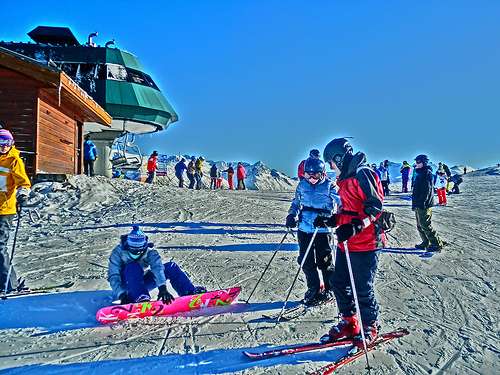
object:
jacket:
[284, 175, 346, 234]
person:
[312, 134, 386, 344]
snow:
[286, 260, 495, 374]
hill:
[227, 160, 297, 193]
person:
[104, 223, 209, 304]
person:
[0, 126, 33, 301]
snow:
[24, 168, 491, 373]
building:
[0, 46, 116, 176]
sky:
[1, 0, 499, 195]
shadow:
[144, 210, 248, 239]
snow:
[400, 254, 498, 349]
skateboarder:
[93, 284, 243, 326]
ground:
[18, 169, 498, 366]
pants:
[120, 261, 197, 305]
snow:
[0, 135, 495, 374]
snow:
[172, 203, 258, 253]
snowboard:
[99, 279, 239, 330]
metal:
[109, 129, 143, 170]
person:
[410, 153, 445, 253]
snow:
[4, 158, 498, 365]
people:
[0, 119, 468, 354]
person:
[235, 164, 248, 191]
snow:
[186, 191, 280, 204]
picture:
[2, 1, 496, 373]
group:
[142, 148, 250, 190]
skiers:
[319, 139, 388, 348]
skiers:
[284, 149, 345, 301]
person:
[144, 150, 158, 184]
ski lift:
[108, 134, 141, 173]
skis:
[244, 327, 408, 374]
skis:
[267, 288, 332, 322]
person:
[283, 149, 344, 309]